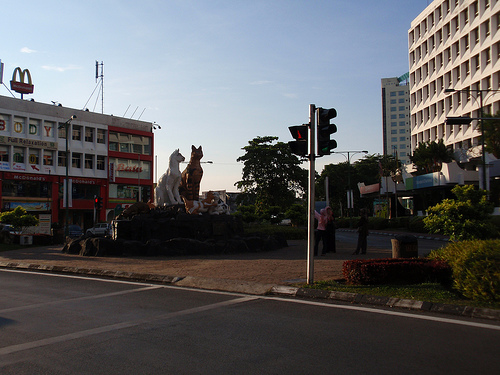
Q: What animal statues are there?
A: Cats.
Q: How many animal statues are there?
A: Two.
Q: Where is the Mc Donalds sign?
A: On the roof.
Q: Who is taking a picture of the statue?
A: The people.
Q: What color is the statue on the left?
A: White.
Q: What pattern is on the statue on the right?
A: Stripes.